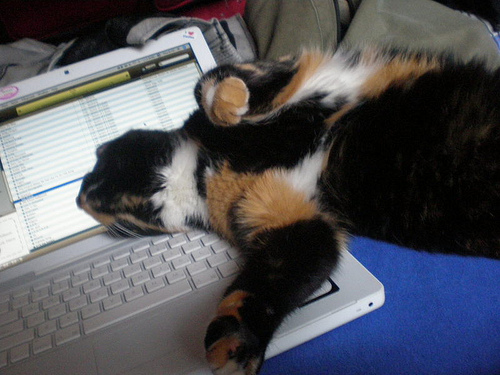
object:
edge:
[347, 250, 387, 323]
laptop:
[0, 19, 389, 372]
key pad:
[1, 226, 205, 364]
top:
[387, 263, 498, 375]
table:
[385, 259, 500, 375]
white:
[168, 141, 197, 228]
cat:
[74, 43, 499, 375]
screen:
[0, 26, 240, 267]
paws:
[200, 300, 282, 375]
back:
[349, 125, 500, 225]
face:
[75, 123, 188, 241]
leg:
[198, 182, 344, 375]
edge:
[330, 218, 348, 271]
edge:
[4, 356, 212, 372]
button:
[119, 281, 150, 303]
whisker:
[99, 213, 144, 247]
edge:
[258, 354, 273, 369]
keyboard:
[1, 226, 251, 375]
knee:
[290, 223, 342, 259]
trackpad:
[87, 293, 222, 374]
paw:
[198, 72, 254, 130]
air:
[108, 311, 203, 373]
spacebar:
[82, 278, 196, 334]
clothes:
[240, 0, 497, 48]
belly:
[309, 85, 496, 203]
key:
[50, 303, 68, 316]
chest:
[238, 115, 312, 170]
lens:
[0, 151, 22, 226]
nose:
[74, 189, 82, 209]